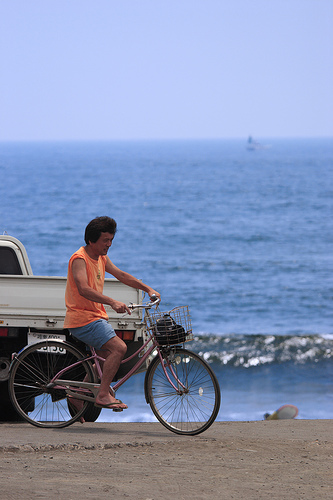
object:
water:
[0, 138, 332, 421]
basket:
[143, 303, 194, 347]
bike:
[7, 292, 222, 434]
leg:
[95, 320, 127, 388]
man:
[64, 215, 159, 422]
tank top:
[63, 244, 107, 330]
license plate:
[28, 327, 65, 352]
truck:
[0, 233, 150, 422]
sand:
[0, 418, 332, 499]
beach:
[0, 418, 332, 498]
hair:
[84, 215, 115, 245]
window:
[0, 245, 25, 277]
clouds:
[0, 0, 332, 140]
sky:
[0, 0, 332, 140]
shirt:
[63, 244, 108, 329]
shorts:
[70, 318, 116, 350]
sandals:
[91, 397, 123, 409]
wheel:
[145, 348, 221, 436]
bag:
[154, 312, 184, 345]